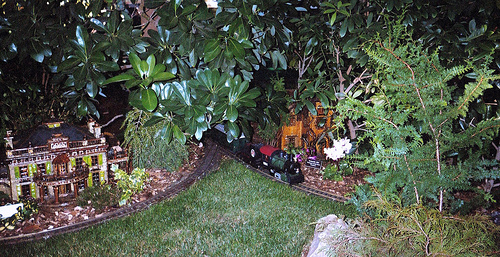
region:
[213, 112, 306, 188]
A train under the tree.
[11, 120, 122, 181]
A toy building under the tree.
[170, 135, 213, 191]
Train tracks around the ground.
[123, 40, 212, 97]
Leaves on the tree.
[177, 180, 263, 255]
The grass is freshly cut.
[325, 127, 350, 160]
White flower on the tree.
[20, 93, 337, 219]
A train set on the ground.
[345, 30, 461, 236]
A little tree covering the tracks.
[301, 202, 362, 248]
A rock on the grass.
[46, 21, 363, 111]
The trees is green.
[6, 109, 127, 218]
This is a building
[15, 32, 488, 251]
This is a homestead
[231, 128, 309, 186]
train under the tree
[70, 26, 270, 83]
tree with leaves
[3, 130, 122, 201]
toy house unser the tree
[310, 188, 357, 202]
toy train track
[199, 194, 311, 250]
green grass between tracks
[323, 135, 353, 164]
flowers in the plant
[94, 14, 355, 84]
trees with branches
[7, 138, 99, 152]
top of the toys house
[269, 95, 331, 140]
toy house under the tree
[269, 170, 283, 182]
wheel of the toy train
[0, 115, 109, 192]
small replica of building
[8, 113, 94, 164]
black roof on building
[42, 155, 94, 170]
windows on front of building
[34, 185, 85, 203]
brown columns on bottom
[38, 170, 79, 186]
small balcony above entrance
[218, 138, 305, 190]
green and black train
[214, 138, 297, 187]
green and black train on tracks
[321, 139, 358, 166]
white flower on bushes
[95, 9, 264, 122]
large green leaves on plants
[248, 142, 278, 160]
red top on train car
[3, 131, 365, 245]
The train tracks diverge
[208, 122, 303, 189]
A train on the tracks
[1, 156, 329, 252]
Grass by the train tracks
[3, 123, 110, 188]
A yellow house by the train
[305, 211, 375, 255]
A rock on the grass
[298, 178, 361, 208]
Tracks beneath the train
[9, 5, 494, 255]
A tree above the train set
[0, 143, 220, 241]
A track with no train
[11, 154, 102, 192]
Windows on the house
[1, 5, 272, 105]
Leaves on the tree